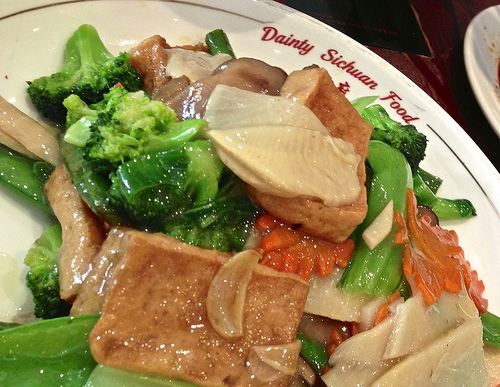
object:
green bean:
[371, 148, 406, 204]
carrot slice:
[392, 186, 462, 303]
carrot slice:
[457, 259, 490, 313]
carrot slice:
[370, 292, 399, 327]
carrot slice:
[327, 324, 352, 362]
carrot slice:
[254, 212, 354, 280]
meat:
[245, 65, 377, 244]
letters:
[258, 24, 421, 123]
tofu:
[89, 229, 315, 385]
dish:
[4, 1, 500, 367]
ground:
[429, 134, 484, 174]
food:
[0, 25, 499, 386]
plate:
[450, 15, 498, 130]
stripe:
[1, 3, 496, 234]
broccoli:
[24, 25, 144, 126]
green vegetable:
[58, 87, 113, 137]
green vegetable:
[354, 95, 429, 167]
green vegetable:
[0, 313, 106, 384]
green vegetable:
[298, 329, 330, 369]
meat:
[126, 34, 176, 86]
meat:
[324, 293, 490, 387]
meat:
[43, 161, 111, 302]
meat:
[165, 44, 236, 85]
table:
[340, 5, 491, 144]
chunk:
[87, 231, 312, 386]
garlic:
[204, 247, 258, 339]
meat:
[88, 226, 313, 383]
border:
[219, 8, 494, 218]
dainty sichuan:
[261, 20, 381, 96]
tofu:
[244, 63, 373, 245]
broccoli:
[57, 87, 207, 164]